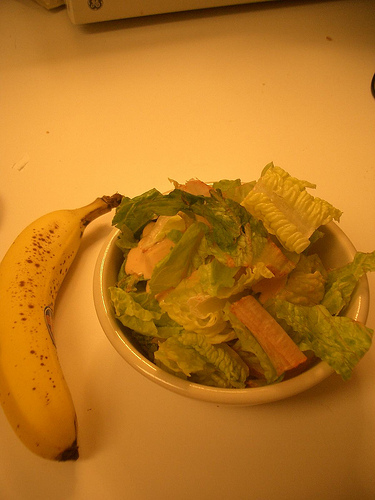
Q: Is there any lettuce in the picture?
A: Yes, there is lettuce.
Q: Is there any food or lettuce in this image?
A: Yes, there is lettuce.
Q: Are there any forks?
A: No, there are no forks.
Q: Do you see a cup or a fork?
A: No, there are no forks or cups.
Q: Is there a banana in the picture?
A: Yes, there is a banana.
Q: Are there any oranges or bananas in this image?
A: Yes, there is a banana.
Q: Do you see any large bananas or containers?
A: Yes, there is a large banana.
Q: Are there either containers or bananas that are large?
A: Yes, the banana is large.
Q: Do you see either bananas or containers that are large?
A: Yes, the banana is large.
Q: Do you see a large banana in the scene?
A: Yes, there is a large banana.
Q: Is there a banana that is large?
A: Yes, there is a banana that is large.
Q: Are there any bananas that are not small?
A: Yes, there is a large banana.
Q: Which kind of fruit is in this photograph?
A: The fruit is a banana.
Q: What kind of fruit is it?
A: The fruit is a banana.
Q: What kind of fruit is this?
A: This is a banana.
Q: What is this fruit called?
A: This is a banana.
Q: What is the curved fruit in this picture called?
A: The fruit is a banana.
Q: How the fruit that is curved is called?
A: The fruit is a banana.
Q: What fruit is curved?
A: The fruit is a banana.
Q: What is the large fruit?
A: The fruit is a banana.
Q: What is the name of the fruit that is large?
A: The fruit is a banana.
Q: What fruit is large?
A: The fruit is a banana.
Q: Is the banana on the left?
A: Yes, the banana is on the left of the image.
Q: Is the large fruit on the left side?
A: Yes, the banana is on the left of the image.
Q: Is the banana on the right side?
A: No, the banana is on the left of the image.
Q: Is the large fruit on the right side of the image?
A: No, the banana is on the left of the image.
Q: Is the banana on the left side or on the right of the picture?
A: The banana is on the left of the image.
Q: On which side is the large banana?
A: The banana is on the left of the image.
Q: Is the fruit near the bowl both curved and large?
A: Yes, the banana is curved and large.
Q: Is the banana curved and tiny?
A: No, the banana is curved but large.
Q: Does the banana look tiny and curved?
A: No, the banana is curved but large.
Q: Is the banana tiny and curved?
A: No, the banana is curved but large.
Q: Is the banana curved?
A: Yes, the banana is curved.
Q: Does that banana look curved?
A: Yes, the banana is curved.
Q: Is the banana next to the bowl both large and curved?
A: Yes, the banana is large and curved.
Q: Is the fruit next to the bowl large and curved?
A: Yes, the banana is large and curved.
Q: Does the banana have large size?
A: Yes, the banana is large.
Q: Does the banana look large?
A: Yes, the banana is large.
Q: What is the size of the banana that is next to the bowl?
A: The banana is large.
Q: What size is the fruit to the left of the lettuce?
A: The banana is large.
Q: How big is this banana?
A: The banana is large.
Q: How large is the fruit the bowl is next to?
A: The banana is large.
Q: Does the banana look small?
A: No, the banana is large.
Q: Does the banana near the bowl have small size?
A: No, the banana is large.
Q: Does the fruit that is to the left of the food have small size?
A: No, the banana is large.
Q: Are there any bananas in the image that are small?
A: No, there is a banana but it is large.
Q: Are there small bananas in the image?
A: No, there is a banana but it is large.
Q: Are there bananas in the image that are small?
A: No, there is a banana but it is large.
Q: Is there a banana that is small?
A: No, there is a banana but it is large.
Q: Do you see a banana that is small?
A: No, there is a banana but it is large.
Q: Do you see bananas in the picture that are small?
A: No, there is a banana but it is large.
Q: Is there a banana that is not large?
A: No, there is a banana but it is large.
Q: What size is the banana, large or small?
A: The banana is large.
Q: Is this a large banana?
A: Yes, this is a large banana.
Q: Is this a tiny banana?
A: No, this is a large banana.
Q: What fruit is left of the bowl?
A: The fruit is a banana.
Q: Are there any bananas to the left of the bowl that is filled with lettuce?
A: Yes, there is a banana to the left of the bowl.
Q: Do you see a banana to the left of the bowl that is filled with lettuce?
A: Yes, there is a banana to the left of the bowl.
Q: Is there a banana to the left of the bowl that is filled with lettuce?
A: Yes, there is a banana to the left of the bowl.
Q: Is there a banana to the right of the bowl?
A: No, the banana is to the left of the bowl.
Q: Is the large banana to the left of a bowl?
A: Yes, the banana is to the left of a bowl.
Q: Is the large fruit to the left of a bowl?
A: Yes, the banana is to the left of a bowl.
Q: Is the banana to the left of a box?
A: No, the banana is to the left of a bowl.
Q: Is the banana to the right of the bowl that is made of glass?
A: No, the banana is to the left of the bowl.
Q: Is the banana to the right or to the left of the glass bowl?
A: The banana is to the left of the bowl.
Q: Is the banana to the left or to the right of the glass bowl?
A: The banana is to the left of the bowl.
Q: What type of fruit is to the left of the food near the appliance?
A: The fruit is a banana.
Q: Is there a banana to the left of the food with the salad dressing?
A: Yes, there is a banana to the left of the food.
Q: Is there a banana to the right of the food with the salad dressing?
A: No, the banana is to the left of the food.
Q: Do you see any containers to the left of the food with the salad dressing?
A: No, there is a banana to the left of the food.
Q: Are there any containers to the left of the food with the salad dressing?
A: No, there is a banana to the left of the food.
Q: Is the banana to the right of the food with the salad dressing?
A: No, the banana is to the left of the food.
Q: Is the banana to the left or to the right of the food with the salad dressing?
A: The banana is to the left of the food.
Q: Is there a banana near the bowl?
A: Yes, there is a banana near the bowl.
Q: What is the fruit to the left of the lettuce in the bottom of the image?
A: The fruit is a banana.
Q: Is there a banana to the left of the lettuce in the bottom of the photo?
A: Yes, there is a banana to the left of the lettuce.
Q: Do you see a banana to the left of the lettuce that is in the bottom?
A: Yes, there is a banana to the left of the lettuce.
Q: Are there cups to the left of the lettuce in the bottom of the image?
A: No, there is a banana to the left of the lettuce.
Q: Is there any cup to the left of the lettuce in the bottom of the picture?
A: No, there is a banana to the left of the lettuce.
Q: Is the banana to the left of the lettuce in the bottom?
A: Yes, the banana is to the left of the lettuce.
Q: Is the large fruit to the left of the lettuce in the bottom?
A: Yes, the banana is to the left of the lettuce.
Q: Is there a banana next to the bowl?
A: Yes, there is a banana next to the bowl.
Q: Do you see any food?
A: Yes, there is food.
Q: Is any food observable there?
A: Yes, there is food.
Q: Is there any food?
A: Yes, there is food.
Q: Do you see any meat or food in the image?
A: Yes, there is food.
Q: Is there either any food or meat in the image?
A: Yes, there is food.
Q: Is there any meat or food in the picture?
A: Yes, there is food.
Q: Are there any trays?
A: No, there are no trays.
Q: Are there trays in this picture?
A: No, there are no trays.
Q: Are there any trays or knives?
A: No, there are no trays or knives.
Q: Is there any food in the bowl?
A: Yes, there is food in the bowl.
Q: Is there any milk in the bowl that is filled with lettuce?
A: No, there is food in the bowl.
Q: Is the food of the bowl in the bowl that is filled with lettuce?
A: Yes, the food is in the bowl.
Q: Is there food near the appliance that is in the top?
A: Yes, there is food near the appliance.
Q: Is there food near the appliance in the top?
A: Yes, there is food near the appliance.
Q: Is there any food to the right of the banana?
A: Yes, there is food to the right of the banana.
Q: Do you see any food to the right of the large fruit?
A: Yes, there is food to the right of the banana.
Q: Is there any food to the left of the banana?
A: No, the food is to the right of the banana.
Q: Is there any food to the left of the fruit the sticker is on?
A: No, the food is to the right of the banana.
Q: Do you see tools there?
A: No, there are no tools.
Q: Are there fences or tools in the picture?
A: No, there are no tools or fences.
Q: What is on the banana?
A: The sticker is on the banana.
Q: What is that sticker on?
A: The sticker is on the banana.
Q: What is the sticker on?
A: The sticker is on the banana.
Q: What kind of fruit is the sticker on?
A: The sticker is on the banana.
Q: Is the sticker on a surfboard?
A: No, the sticker is on a banana.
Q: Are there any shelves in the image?
A: No, there are no shelves.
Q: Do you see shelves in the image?
A: No, there are no shelves.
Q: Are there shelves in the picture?
A: No, there are no shelves.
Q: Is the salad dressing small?
A: Yes, the salad dressing is small.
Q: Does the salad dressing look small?
A: Yes, the salad dressing is small.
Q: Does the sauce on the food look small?
A: Yes, the salad dressing is small.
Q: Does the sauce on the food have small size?
A: Yes, the salad dressing is small.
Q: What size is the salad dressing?
A: The salad dressing is small.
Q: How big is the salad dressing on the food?
A: The salad dressing is small.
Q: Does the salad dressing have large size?
A: No, the salad dressing is small.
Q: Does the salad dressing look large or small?
A: The salad dressing is small.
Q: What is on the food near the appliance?
A: The salad dressing is on the food.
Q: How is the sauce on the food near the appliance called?
A: The sauce is a salad dressing.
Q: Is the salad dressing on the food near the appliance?
A: Yes, the salad dressing is on the food.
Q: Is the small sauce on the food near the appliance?
A: Yes, the salad dressing is on the food.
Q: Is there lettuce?
A: Yes, there is lettuce.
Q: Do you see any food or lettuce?
A: Yes, there is lettuce.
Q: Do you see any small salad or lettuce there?
A: Yes, there is small lettuce.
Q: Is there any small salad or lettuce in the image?
A: Yes, there is small lettuce.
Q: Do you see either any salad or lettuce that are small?
A: Yes, the lettuce is small.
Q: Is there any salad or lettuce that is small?
A: Yes, the lettuce is small.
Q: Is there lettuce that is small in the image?
A: Yes, there is small lettuce.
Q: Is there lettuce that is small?
A: Yes, there is lettuce that is small.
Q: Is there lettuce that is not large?
A: Yes, there is small lettuce.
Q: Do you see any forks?
A: No, there are no forks.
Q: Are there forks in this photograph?
A: No, there are no forks.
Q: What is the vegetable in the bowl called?
A: The vegetable is lettuce.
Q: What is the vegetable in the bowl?
A: The vegetable is lettuce.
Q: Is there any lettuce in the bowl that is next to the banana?
A: Yes, there is lettuce in the bowl.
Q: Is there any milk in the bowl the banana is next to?
A: No, there is lettuce in the bowl.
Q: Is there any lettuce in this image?
A: Yes, there is lettuce.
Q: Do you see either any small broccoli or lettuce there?
A: Yes, there is small lettuce.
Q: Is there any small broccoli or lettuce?
A: Yes, there is small lettuce.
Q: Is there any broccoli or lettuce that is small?
A: Yes, the lettuce is small.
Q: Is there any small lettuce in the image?
A: Yes, there is small lettuce.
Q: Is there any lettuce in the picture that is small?
A: Yes, there is small lettuce.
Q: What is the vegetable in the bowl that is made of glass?
A: The vegetable is lettuce.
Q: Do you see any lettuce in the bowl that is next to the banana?
A: Yes, there is lettuce in the bowl.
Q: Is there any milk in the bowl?
A: No, there is lettuce in the bowl.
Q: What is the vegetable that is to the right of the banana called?
A: The vegetable is lettuce.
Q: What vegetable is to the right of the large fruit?
A: The vegetable is lettuce.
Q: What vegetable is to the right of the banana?
A: The vegetable is lettuce.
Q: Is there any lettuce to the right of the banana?
A: Yes, there is lettuce to the right of the banana.